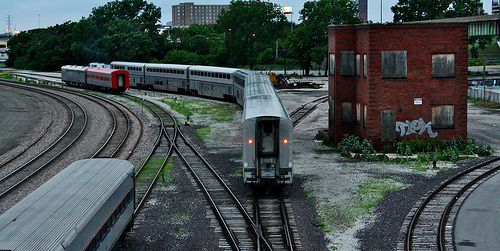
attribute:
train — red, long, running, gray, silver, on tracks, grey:
[97, 56, 300, 193]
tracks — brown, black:
[3, 80, 491, 247]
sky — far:
[0, 0, 499, 37]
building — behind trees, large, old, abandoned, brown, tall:
[174, 0, 285, 34]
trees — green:
[9, 0, 351, 80]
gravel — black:
[362, 165, 406, 249]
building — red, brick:
[327, 24, 465, 152]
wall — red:
[365, 23, 467, 147]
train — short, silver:
[112, 58, 297, 184]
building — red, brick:
[323, 20, 472, 151]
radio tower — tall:
[5, 12, 15, 33]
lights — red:
[250, 126, 296, 159]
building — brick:
[339, 17, 470, 167]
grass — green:
[189, 107, 234, 141]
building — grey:
[168, 0, 216, 40]